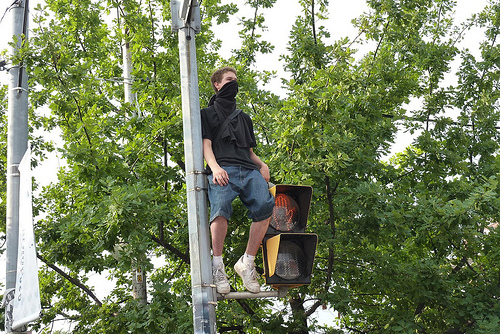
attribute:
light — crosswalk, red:
[261, 165, 351, 327]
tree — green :
[20, 20, 480, 322]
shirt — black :
[178, 85, 309, 175]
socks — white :
[197, 234, 304, 305]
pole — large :
[157, 22, 265, 330]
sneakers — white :
[227, 252, 273, 303]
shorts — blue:
[210, 160, 265, 220]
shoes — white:
[213, 256, 273, 291]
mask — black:
[217, 86, 254, 102]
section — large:
[303, 11, 461, 222]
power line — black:
[256, 70, 484, 149]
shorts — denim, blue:
[203, 163, 283, 225]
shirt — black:
[192, 100, 271, 163]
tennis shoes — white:
[187, 244, 265, 289]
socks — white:
[214, 251, 257, 262]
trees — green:
[8, 3, 484, 322]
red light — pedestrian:
[251, 177, 327, 291]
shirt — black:
[185, 98, 277, 168]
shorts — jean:
[206, 170, 274, 221]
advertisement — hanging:
[5, 141, 89, 330]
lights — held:
[281, 196, 309, 243]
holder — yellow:
[249, 172, 329, 266]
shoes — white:
[195, 238, 298, 316]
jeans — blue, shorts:
[192, 170, 289, 223]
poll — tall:
[151, 66, 229, 303]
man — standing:
[196, 73, 299, 283]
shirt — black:
[196, 90, 256, 164]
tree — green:
[259, 90, 387, 186]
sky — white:
[303, 2, 401, 90]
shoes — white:
[203, 243, 305, 305]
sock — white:
[207, 248, 269, 287]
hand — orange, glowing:
[255, 185, 311, 235]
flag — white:
[7, 150, 77, 308]